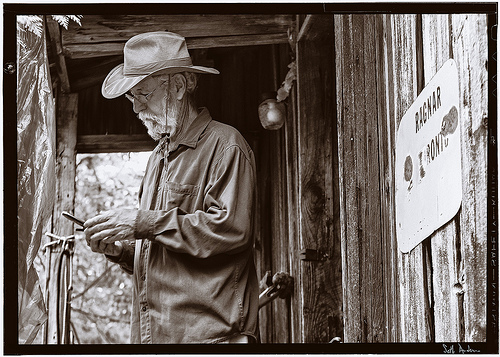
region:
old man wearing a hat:
[83, 19, 219, 351]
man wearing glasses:
[109, 55, 194, 227]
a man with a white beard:
[102, 23, 234, 181]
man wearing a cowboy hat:
[99, 28, 295, 320]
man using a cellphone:
[57, 34, 281, 294]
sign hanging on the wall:
[351, 83, 492, 264]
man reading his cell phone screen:
[86, 31, 293, 336]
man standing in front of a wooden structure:
[55, 30, 482, 327]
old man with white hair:
[72, 31, 289, 333]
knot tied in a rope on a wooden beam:
[36, 33, 116, 332]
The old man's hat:
[92, 28, 224, 102]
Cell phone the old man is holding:
[57, 207, 85, 232]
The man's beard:
[140, 111, 179, 147]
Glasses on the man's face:
[123, 78, 167, 108]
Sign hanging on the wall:
[375, 55, 464, 257]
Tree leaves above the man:
[3, 11, 88, 41]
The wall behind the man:
[254, 16, 489, 341]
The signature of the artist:
[440, 337, 478, 352]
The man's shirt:
[128, 106, 264, 341]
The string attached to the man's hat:
[159, 71, 175, 176]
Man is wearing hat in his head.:
[92, 33, 200, 93]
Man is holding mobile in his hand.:
[60, 207, 125, 262]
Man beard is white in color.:
[157, 120, 172, 135]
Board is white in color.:
[390, 112, 465, 212]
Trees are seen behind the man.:
[85, 173, 136, 210]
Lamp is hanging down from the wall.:
[245, 75, 287, 130]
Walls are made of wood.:
[295, 147, 380, 277]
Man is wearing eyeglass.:
[118, 82, 158, 109]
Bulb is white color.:
[260, 95, 286, 132]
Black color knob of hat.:
[156, 128, 179, 145]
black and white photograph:
[18, 16, 487, 340]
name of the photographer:
[439, 343, 486, 355]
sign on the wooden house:
[384, 58, 462, 254]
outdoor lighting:
[254, 98, 289, 127]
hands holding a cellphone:
[59, 208, 137, 254]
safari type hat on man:
[91, 30, 221, 144]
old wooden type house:
[41, 14, 494, 348]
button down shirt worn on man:
[133, 116, 259, 339]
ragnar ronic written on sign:
[414, 89, 449, 162]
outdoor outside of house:
[18, 143, 143, 342]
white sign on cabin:
[374, 51, 464, 252]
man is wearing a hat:
[95, 29, 222, 101]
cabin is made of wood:
[52, 9, 491, 342]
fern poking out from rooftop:
[16, 12, 90, 39]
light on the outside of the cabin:
[254, 84, 285, 136]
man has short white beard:
[136, 98, 183, 140]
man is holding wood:
[57, 201, 136, 253]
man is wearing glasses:
[121, 78, 176, 108]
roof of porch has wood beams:
[52, 9, 306, 59]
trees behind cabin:
[74, 146, 195, 347]